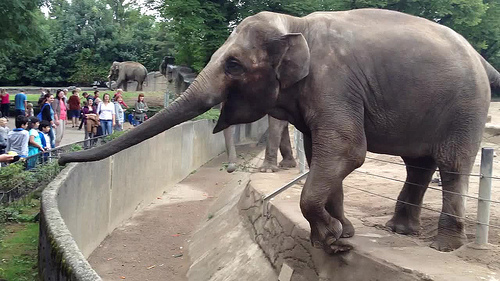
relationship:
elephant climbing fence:
[60, 9, 500, 254] [223, 123, 500, 250]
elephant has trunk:
[60, 9, 500, 254] [57, 79, 216, 166]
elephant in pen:
[60, 9, 500, 254] [40, 104, 499, 280]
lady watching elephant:
[53, 89, 71, 149] [60, 9, 500, 254]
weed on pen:
[37, 198, 81, 280] [40, 104, 499, 280]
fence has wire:
[223, 123, 500, 250] [295, 130, 500, 230]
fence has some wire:
[223, 123, 500, 250] [295, 130, 500, 230]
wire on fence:
[295, 130, 500, 230] [223, 123, 500, 250]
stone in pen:
[236, 169, 425, 280] [40, 104, 499, 280]